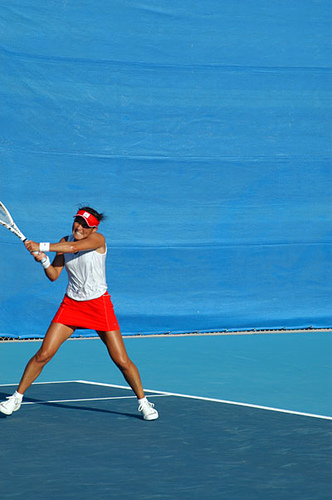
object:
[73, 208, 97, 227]
visor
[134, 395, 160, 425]
tennis shoe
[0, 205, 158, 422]
female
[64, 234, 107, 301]
blouse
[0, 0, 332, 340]
blue wall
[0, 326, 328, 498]
field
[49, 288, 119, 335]
female skirt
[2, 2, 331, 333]
wall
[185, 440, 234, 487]
part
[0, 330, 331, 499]
floor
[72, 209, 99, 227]
cap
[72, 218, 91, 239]
face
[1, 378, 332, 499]
bottom floor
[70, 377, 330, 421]
lines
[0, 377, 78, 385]
lines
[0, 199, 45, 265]
racket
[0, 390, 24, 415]
sneakers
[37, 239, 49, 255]
armbands